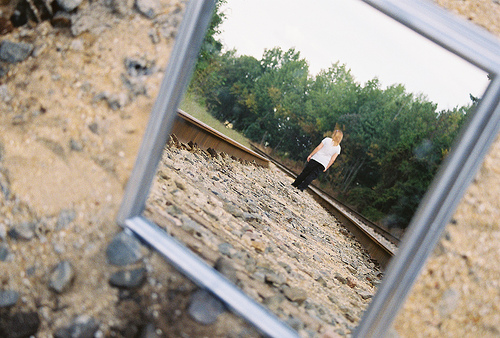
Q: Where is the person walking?
A: Railroad tracks.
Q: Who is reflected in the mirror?
A: A woman.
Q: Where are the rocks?
A: In the tracks.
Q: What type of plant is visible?
A: Tree.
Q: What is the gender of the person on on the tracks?
A: Female.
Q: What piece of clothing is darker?
A: Pants.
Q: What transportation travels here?
A: Train.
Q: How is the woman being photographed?
A: Using a mirror.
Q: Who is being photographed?
A: A woman.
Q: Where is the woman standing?
A: On train tracks.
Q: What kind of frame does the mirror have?
A: A silver color frame.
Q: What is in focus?
A: Only what is reflected by the mirror.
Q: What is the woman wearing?
A: White shirt, black pants.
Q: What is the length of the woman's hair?
A: Medium.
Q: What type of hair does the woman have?
A: Blond.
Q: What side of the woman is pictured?
A: Back.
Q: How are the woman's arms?
A: Straight down.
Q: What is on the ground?
A: Mirror.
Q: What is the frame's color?
A: Silver.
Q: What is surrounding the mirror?
A: Frame.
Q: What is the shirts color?
A: White.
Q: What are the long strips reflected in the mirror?
A: Train tracks.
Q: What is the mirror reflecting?
A: A girl.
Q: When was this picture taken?
A: Daytime.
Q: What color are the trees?
A: Green.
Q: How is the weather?
A: Overcast.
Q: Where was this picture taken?
A: A railway.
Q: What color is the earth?
A: Brown.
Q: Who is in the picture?
A: A girl.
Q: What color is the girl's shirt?
A: White.